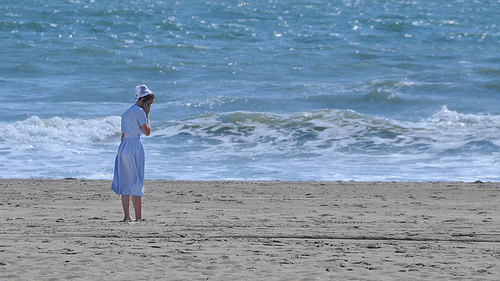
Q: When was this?
A: Daytime.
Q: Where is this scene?
A: Beach.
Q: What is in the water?
A: Waves.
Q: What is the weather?
A: Sunny.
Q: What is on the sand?
A: Trails.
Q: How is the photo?
A: Clear.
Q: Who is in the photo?
A: A person.